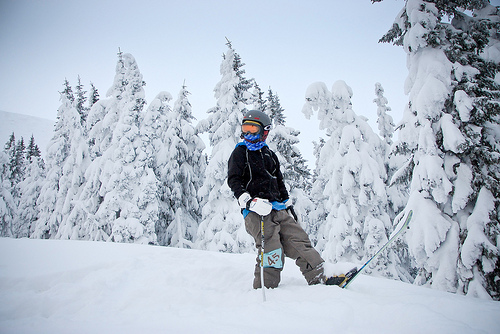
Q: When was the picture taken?
A: In the day time.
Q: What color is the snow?
A: White.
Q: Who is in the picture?
A: A skiier.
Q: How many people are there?
A: 1.